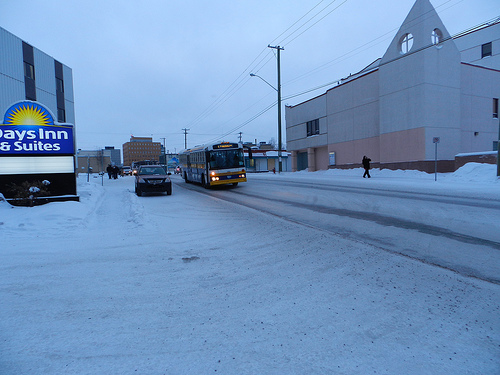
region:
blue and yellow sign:
[3, 118, 79, 165]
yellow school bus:
[175, 145, 247, 192]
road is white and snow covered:
[237, 169, 480, 372]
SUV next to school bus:
[118, 151, 174, 191]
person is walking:
[360, 150, 373, 177]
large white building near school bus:
[285, 22, 499, 177]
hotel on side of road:
[0, 91, 87, 201]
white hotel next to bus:
[9, 33, 80, 157]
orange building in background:
[112, 125, 165, 161]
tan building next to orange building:
[74, 146, 125, 172]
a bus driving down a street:
[181, 124, 264, 199]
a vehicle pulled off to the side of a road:
[135, 151, 172, 206]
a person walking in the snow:
[350, 148, 384, 191]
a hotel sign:
[0, 87, 85, 219]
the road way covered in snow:
[198, 180, 377, 302]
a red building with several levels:
[116, 130, 166, 170]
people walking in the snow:
[103, 157, 128, 181]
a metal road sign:
[419, 126, 446, 187]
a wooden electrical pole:
[246, 27, 298, 151]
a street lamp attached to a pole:
[241, 35, 293, 139]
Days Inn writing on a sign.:
[0, 126, 70, 141]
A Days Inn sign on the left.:
[1, 101, 76, 155]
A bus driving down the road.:
[176, 141, 248, 190]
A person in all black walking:
[360, 150, 371, 178]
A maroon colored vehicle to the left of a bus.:
[131, 163, 173, 196]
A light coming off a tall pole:
[249, 72, 279, 96]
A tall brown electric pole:
[267, 44, 282, 168]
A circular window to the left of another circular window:
[397, 31, 415, 54]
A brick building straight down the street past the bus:
[120, 137, 167, 171]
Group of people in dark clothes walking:
[106, 163, 118, 178]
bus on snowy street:
[177, 136, 254, 200]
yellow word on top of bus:
[211, 138, 238, 153]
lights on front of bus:
[206, 169, 250, 188]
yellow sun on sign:
[7, 100, 61, 135]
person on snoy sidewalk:
[350, 150, 377, 187]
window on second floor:
[295, 111, 325, 147]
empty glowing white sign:
[2, 153, 82, 178]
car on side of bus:
[130, 159, 199, 201]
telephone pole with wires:
[264, 46, 286, 119]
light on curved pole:
[244, 66, 280, 95]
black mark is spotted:
[177, 250, 195, 273]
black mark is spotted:
[186, 243, 203, 278]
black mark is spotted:
[179, 244, 213, 289]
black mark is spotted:
[176, 252, 246, 339]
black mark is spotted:
[187, 245, 198, 265]